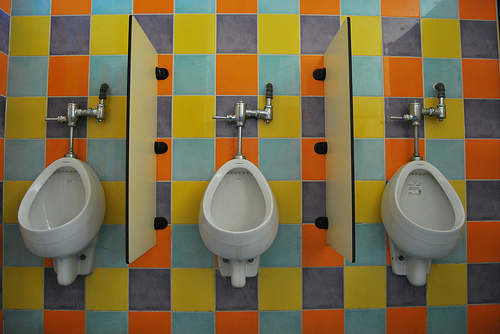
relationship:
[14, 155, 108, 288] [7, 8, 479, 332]
urinal in wall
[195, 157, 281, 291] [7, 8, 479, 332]
urinal in wall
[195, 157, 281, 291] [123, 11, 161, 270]
urinal between urinal divider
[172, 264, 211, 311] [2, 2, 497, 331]
tile in floor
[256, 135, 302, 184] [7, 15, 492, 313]
tile in wall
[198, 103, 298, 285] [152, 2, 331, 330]
urinal against wall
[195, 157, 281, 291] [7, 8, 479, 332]
urinal on wall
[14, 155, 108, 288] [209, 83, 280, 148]
urinal with plumbing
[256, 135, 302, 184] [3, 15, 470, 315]
tile in floor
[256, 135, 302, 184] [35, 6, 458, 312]
tile in floor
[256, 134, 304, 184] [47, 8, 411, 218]
tile in floor